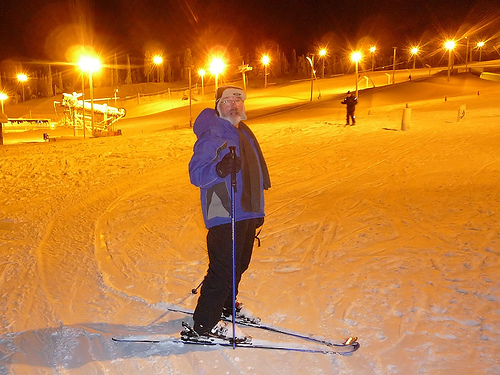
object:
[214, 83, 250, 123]
cap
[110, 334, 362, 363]
ski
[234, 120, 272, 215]
scarf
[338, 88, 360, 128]
man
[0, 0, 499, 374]
background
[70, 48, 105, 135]
street light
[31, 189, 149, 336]
track marks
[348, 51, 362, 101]
street light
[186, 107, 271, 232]
blue jacket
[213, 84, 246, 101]
brown fur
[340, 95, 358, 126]
snow suit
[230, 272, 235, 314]
blue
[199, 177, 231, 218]
gray pattern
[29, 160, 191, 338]
packed snow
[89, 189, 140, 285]
ski marks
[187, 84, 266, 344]
man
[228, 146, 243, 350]
ski pole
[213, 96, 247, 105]
glasses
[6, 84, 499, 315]
snow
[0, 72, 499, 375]
ground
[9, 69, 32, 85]
light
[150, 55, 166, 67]
light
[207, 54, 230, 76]
light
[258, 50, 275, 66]
light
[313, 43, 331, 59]
light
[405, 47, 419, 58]
light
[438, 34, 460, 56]
light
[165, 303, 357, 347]
ski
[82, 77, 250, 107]
fence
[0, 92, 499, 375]
ski slope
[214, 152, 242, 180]
glove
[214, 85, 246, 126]
head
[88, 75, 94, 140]
post